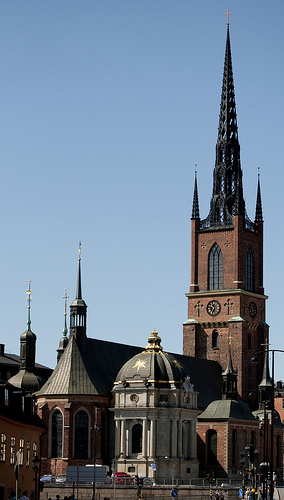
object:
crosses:
[227, 329, 234, 347]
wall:
[186, 290, 241, 318]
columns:
[143, 416, 153, 457]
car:
[109, 469, 135, 485]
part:
[238, 462, 244, 479]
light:
[238, 443, 261, 483]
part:
[149, 431, 153, 443]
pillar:
[148, 418, 155, 457]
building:
[30, 325, 108, 488]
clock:
[205, 300, 222, 317]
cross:
[192, 300, 203, 317]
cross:
[222, 296, 234, 314]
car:
[39, 472, 53, 484]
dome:
[112, 327, 198, 391]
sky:
[50, 97, 124, 203]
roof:
[26, 334, 107, 396]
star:
[129, 356, 150, 372]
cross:
[220, 8, 232, 27]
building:
[186, 10, 264, 395]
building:
[5, 278, 38, 426]